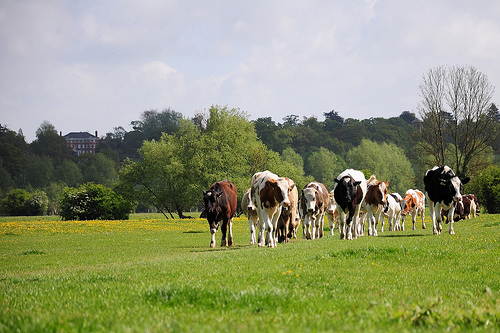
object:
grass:
[0, 212, 497, 332]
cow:
[200, 180, 237, 250]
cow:
[248, 168, 288, 249]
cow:
[240, 187, 261, 247]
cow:
[299, 181, 330, 240]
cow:
[274, 177, 303, 244]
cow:
[360, 175, 391, 237]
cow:
[401, 188, 428, 233]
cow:
[456, 192, 480, 222]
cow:
[421, 163, 466, 235]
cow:
[329, 166, 370, 240]